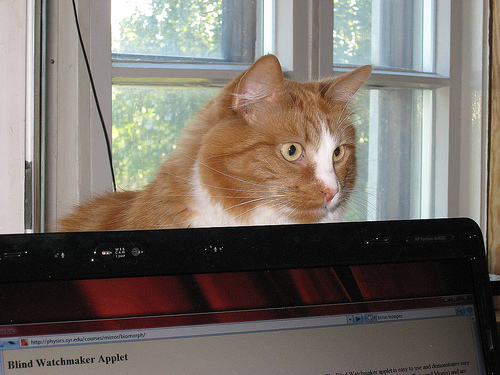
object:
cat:
[56, 53, 374, 234]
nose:
[321, 187, 339, 202]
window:
[43, 0, 462, 233]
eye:
[281, 141, 304, 162]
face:
[248, 94, 358, 222]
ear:
[232, 53, 285, 115]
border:
[0, 214, 499, 374]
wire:
[71, 1, 118, 193]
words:
[35, 358, 47, 367]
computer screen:
[0, 257, 491, 374]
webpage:
[0, 290, 484, 374]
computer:
[0, 217, 497, 374]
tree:
[113, 0, 218, 188]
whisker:
[164, 169, 277, 194]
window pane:
[338, 87, 434, 221]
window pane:
[112, 85, 225, 194]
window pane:
[112, 0, 279, 62]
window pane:
[334, 0, 438, 72]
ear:
[319, 64, 374, 101]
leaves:
[131, 90, 175, 122]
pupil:
[288, 145, 295, 156]